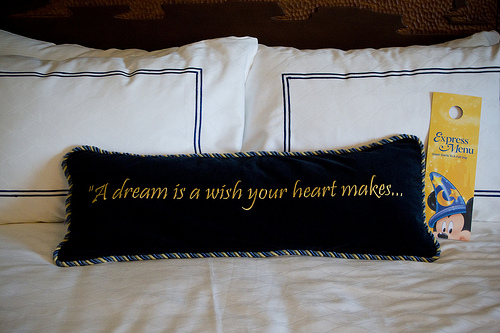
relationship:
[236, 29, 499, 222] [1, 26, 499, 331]
pillow on bed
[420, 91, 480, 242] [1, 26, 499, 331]
door hanger on bed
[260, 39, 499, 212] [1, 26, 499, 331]
pillow on bed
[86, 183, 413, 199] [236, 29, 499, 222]
words on pillow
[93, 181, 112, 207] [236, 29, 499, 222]
letter on pillow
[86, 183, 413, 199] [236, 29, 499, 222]
phrase on pillow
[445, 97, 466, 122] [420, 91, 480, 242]
hole of door hanger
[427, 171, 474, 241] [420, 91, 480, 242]
mickey mouse on door hanger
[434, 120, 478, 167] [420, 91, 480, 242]
phrase on door hanger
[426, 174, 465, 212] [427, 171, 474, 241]
hat on mickey mouse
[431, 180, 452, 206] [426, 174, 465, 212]
print on hat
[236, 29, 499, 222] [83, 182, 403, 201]
pillow with lettering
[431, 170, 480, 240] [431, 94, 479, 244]
mickey mouse on bag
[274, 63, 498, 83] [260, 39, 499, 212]
trim on pillow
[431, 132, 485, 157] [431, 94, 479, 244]
letters on bag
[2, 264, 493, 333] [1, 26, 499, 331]
blanket of bed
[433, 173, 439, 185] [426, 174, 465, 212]
stars on hat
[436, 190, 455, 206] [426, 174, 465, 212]
moons on hat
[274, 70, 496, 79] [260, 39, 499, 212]
lines on pillow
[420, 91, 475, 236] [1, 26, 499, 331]
door hanger on bed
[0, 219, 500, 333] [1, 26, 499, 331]
blanket on bed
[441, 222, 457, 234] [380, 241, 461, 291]
eyes are two